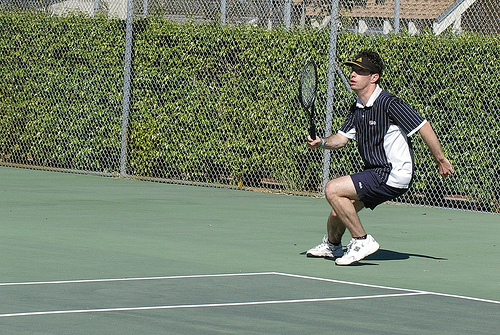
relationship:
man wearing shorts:
[296, 48, 451, 263] [349, 170, 402, 213]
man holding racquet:
[296, 48, 451, 263] [299, 60, 321, 137]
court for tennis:
[5, 163, 499, 333] [7, 24, 497, 332]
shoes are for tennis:
[307, 237, 382, 266] [7, 24, 497, 332]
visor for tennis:
[342, 57, 379, 74] [7, 24, 497, 332]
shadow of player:
[302, 242, 446, 265] [296, 48, 451, 263]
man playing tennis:
[296, 48, 451, 263] [7, 24, 497, 332]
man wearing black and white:
[296, 48, 451, 263] [343, 90, 430, 190]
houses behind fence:
[30, 2, 497, 43] [0, 0, 499, 216]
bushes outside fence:
[0, 0, 499, 216] [25, 16, 481, 196]